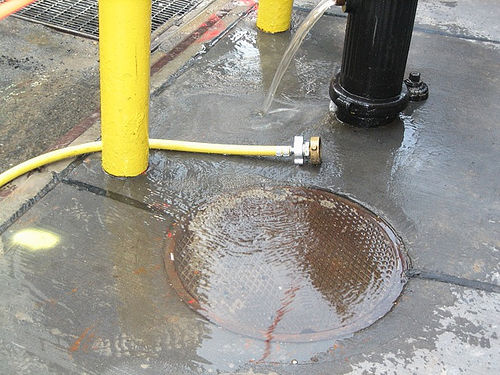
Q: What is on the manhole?
A: Water.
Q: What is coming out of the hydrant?
A: Water.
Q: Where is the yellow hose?
A: On the ground.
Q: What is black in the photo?
A: Fire hydrant.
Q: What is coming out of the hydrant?
A: Water.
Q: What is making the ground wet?
A: Water.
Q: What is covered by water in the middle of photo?
A: Manhole.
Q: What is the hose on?
A: Cement.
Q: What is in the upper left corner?
A: Grid.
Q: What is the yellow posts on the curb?
A: Parking post.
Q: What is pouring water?
A: Fire hydrant.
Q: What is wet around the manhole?
A: Sidewalk.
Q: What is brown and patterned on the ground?
A: Manhole.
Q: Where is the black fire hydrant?
A: On the sidewalk.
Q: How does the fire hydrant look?
A: Open.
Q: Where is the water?
A: On the pavement.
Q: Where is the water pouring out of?
A: Hydrant.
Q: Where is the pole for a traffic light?
A: On the sidewalk.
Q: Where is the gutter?
A: By the walkway.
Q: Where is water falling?
A: On the floor.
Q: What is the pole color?
A: Yellow.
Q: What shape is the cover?
A: Round.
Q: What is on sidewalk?
A: Water.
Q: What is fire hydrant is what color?
A: Black.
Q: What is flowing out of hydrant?
A: Water.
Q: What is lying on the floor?
A: Hose.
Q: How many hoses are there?
A: 1.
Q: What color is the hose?
A: Yellow.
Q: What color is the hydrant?
A: Black.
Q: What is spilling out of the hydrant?
A: Water.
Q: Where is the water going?
A: Down the manhole.